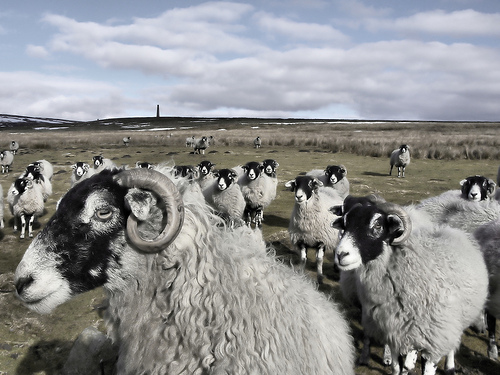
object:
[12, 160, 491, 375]
ram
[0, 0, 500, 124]
sky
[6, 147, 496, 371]
field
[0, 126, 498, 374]
sheep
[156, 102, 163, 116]
silo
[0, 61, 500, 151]
distance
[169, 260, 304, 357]
wool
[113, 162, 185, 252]
horn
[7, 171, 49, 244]
sheep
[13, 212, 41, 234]
shadow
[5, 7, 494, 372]
weather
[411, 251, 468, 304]
fur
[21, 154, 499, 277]
horns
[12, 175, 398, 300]
faces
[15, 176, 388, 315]
regions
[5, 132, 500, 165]
vegetation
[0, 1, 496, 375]
photo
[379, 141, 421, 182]
sheep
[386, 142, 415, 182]
coat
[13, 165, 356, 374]
sheep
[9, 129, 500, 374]
landscape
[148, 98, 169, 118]
structure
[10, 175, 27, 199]
face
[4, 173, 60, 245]
coat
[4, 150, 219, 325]
head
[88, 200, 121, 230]
eye